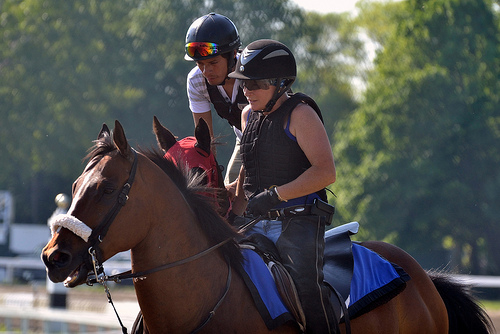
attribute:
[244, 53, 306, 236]
woman — here, jockey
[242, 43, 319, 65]
helmet — here, round, black, gray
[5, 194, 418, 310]
horse — here, brown, standing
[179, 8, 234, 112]
man — here, rider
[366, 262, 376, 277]
blanket — here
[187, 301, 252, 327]
leather — here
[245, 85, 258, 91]
shades — here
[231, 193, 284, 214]
gloves — here, black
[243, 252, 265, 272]
saddle — blue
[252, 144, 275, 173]
vest — black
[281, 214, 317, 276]
pants — pair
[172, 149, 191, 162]
mask — red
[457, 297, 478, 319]
tail — black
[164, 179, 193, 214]
mane — black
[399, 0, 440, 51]
trees — back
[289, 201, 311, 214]
belt — black